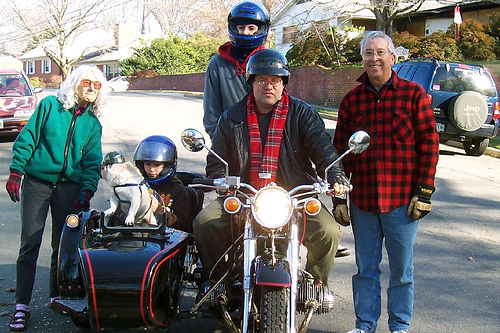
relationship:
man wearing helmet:
[193, 49, 356, 311] [242, 45, 294, 86]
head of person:
[353, 34, 400, 82] [339, 29, 421, 329]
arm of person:
[69, 119, 107, 219] [6, 59, 111, 331]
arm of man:
[183, 114, 244, 203] [193, 49, 356, 311]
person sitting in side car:
[103, 132, 198, 233] [51, 161, 203, 331]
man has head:
[330, 29, 438, 333] [352, 24, 409, 84]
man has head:
[193, 49, 356, 311] [217, 0, 286, 54]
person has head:
[206, 3, 276, 158] [232, 45, 299, 116]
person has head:
[8, 65, 105, 315] [133, 130, 177, 185]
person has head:
[110, 134, 198, 234] [55, 59, 111, 112]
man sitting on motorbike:
[186, 51, 350, 268] [189, 122, 356, 331]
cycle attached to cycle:
[45, 129, 368, 333] [45, 129, 368, 333]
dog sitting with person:
[101, 153, 167, 233] [132, 140, 194, 235]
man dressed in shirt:
[330, 26, 439, 331] [335, 66, 434, 207]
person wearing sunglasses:
[2, 65, 104, 333] [76, 76, 101, 88]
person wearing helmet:
[206, 3, 276, 146] [127, 129, 176, 196]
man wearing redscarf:
[193, 49, 356, 311] [244, 93, 290, 193]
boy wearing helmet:
[137, 134, 190, 217] [131, 134, 178, 188]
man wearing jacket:
[193, 49, 356, 311] [176, 86, 368, 258]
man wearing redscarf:
[193, 49, 356, 311] [234, 97, 296, 185]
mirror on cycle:
[170, 124, 217, 156] [17, 107, 454, 328]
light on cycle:
[295, 184, 340, 228] [176, 167, 386, 315]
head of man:
[243, 47, 293, 109] [330, 29, 438, 333]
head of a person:
[357, 29, 397, 79] [299, 25, 495, 331]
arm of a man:
[302, 106, 339, 176] [193, 49, 356, 311]